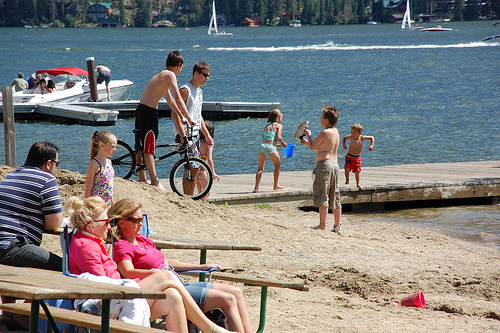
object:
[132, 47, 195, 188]
boy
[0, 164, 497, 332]
beach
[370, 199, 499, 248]
water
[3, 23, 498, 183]
beach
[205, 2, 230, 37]
sail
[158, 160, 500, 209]
boardwalk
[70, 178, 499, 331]
sand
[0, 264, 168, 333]
table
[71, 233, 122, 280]
shirt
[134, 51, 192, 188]
man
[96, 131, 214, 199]
bicycle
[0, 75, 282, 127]
boat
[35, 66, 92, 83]
red canopy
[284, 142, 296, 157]
bucket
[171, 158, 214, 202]
rubber tire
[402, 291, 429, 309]
pail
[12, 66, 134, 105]
boat top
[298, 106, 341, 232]
boy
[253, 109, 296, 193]
girl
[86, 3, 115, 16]
roof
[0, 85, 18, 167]
post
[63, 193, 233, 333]
lady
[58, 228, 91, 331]
chair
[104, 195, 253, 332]
woman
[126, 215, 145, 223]
sunglasses